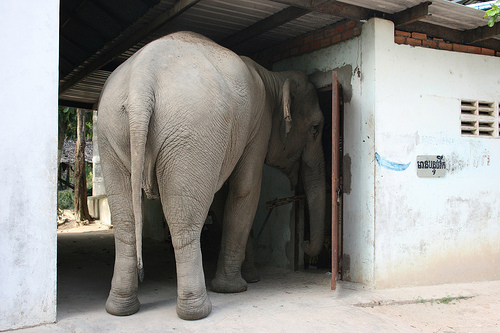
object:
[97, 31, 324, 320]
elephant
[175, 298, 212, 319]
foot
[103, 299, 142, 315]
foot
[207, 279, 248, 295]
foot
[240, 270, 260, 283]
foot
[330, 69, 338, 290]
door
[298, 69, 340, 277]
doorway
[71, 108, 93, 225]
tree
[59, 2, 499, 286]
building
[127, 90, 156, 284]
tail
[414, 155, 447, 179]
sign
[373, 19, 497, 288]
wall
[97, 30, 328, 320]
skin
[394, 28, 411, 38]
brick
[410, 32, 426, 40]
brick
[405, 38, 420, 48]
brick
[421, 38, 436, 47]
brick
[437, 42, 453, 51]
brick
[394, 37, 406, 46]
bricks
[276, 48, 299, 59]
bricks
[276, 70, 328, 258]
head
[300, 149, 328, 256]
trunk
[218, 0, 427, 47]
frame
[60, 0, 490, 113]
ceiling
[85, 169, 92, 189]
grass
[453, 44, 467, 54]
brick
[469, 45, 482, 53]
brick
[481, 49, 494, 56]
brick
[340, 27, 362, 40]
brick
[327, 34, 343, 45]
brick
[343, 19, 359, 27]
brick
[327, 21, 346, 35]
brick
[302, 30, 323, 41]
brick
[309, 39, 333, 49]
brick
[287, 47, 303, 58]
brick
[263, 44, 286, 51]
brick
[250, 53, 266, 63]
brick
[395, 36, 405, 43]
brick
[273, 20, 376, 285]
wall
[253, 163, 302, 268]
wall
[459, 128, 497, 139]
vents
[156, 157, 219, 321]
leg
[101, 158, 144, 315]
leg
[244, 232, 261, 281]
leg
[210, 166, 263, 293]
leg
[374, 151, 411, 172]
paint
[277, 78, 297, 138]
ear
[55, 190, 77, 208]
weeds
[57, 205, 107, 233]
ground